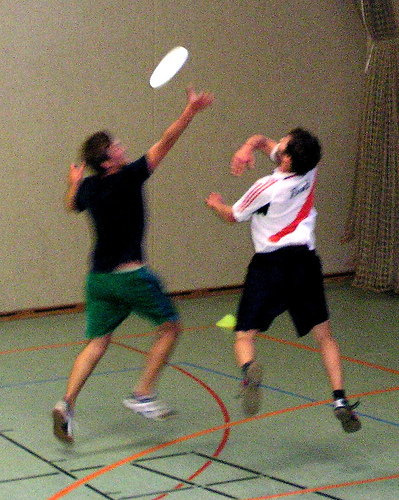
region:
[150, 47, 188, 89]
the frisbee is white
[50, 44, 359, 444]
two guys playing frisbee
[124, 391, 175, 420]
blue and white shoe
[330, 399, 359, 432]
white and black shoe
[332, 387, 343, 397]
the sock is black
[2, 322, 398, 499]
colored lines on ground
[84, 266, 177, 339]
the shorts are green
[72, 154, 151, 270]
the shirt is black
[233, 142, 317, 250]
red and white shirt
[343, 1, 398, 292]
a net is tied closed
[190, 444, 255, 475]
black line on floor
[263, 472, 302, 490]
black line on floor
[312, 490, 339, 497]
black line on floor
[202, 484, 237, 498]
black line on floor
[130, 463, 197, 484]
black line on floor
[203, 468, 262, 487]
black line on floor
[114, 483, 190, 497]
black line on floor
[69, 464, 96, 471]
black line on floor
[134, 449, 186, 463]
black line on floor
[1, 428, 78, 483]
black line on floor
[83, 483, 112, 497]
black line on floor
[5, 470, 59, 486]
black line on floor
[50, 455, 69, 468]
black line on floor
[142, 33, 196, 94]
a frisbee in the air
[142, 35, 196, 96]
a frisbee in color white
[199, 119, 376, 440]
man is jumping in the air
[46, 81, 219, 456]
man jumping in the air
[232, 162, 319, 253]
shirt is white and red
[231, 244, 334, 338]
the shorts are color black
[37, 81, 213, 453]
man has black shirt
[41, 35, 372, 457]
two men jumps to get a frisbee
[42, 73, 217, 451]
man has right hand up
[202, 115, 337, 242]
man has black hair